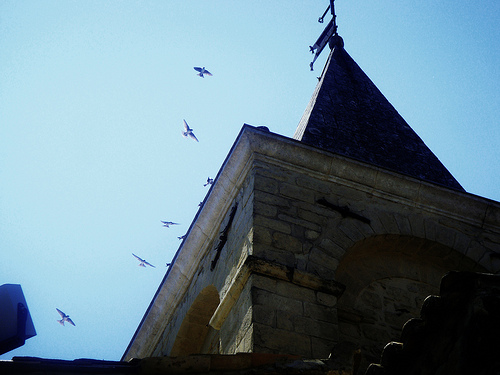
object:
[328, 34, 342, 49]
ball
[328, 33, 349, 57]
tip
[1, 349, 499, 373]
roof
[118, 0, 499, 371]
building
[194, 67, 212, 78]
bird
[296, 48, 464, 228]
roof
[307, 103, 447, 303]
building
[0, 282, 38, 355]
light fixture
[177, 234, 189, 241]
bird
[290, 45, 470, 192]
steeple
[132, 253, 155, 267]
bird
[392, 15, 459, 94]
clouds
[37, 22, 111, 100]
white clouds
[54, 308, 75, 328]
bird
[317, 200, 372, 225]
brace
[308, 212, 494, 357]
arch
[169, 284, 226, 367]
arch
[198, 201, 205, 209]
bird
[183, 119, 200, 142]
bird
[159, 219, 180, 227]
bird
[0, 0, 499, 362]
sky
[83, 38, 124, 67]
sky